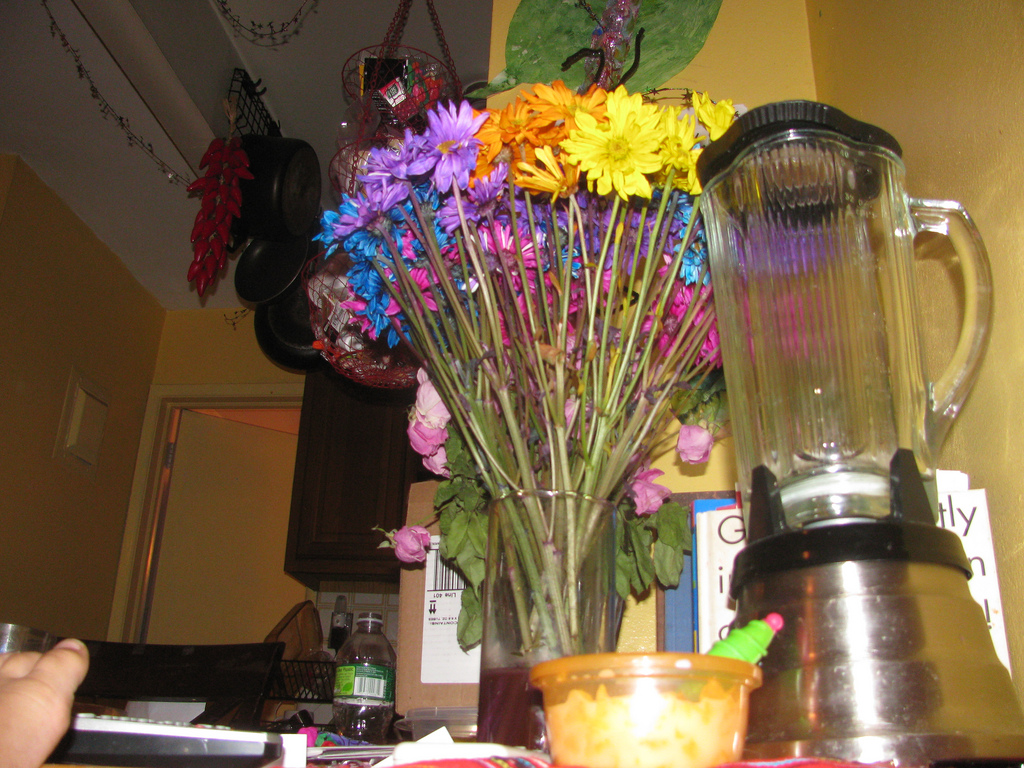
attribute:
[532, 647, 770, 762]
bowl — small, orange